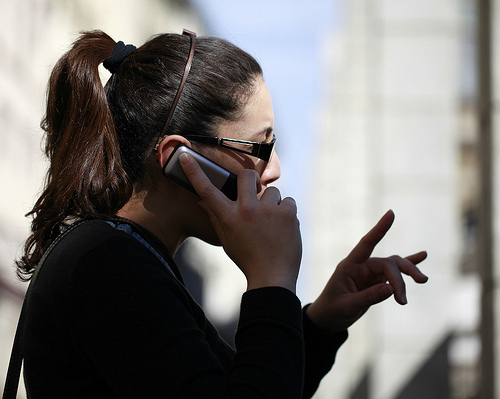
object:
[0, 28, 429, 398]
lady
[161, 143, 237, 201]
phone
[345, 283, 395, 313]
finger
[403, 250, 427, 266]
finger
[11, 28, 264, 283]
hair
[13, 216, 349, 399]
blouse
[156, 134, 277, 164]
spectacles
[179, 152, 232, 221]
finger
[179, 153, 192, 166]
nail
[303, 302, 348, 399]
sleeve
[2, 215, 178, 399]
strap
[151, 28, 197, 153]
band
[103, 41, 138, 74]
holder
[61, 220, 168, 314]
shoulder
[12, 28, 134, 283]
ponytail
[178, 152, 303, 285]
hand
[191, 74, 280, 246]
face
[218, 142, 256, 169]
shadow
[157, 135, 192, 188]
ear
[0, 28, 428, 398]
side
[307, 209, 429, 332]
hand